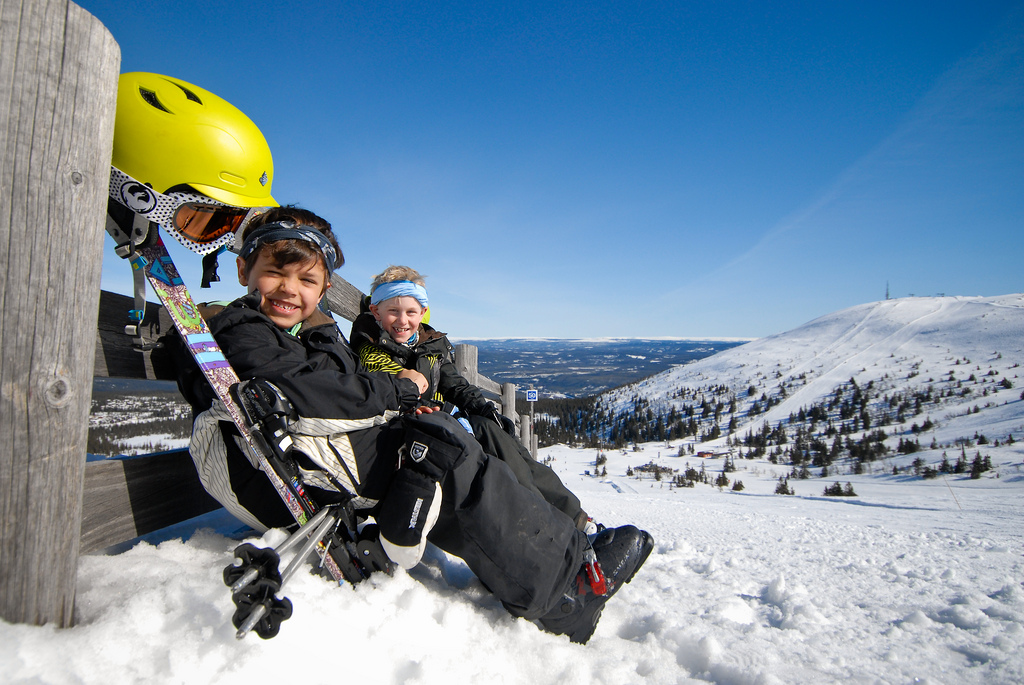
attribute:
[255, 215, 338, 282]
bandanna — black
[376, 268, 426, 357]
bandanna — blue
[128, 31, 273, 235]
helmet — yellow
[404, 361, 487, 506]
gloves — black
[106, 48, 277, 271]
helmet — yellow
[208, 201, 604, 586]
boys — young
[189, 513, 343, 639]
ski poles — metal, snow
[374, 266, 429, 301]
head band — blue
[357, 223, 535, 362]
hair — blonde